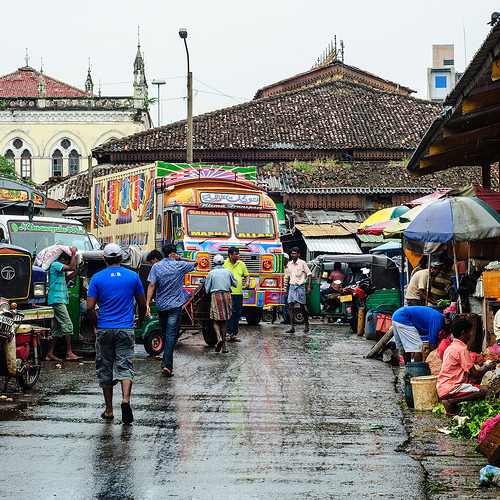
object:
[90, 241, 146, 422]
man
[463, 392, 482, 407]
lettuce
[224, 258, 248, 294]
shirt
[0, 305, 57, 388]
scooter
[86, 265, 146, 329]
shirt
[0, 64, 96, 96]
roof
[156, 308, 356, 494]
road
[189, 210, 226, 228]
windshield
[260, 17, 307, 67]
sky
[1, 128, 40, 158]
arches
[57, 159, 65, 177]
window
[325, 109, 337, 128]
shingles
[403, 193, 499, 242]
umbrella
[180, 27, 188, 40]
light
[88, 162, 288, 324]
bus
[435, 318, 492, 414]
boy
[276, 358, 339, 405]
rain